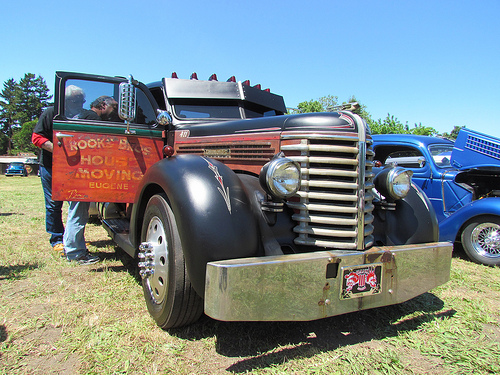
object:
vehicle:
[51, 71, 451, 329]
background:
[0, 0, 500, 268]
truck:
[370, 127, 500, 267]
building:
[0, 156, 38, 176]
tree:
[0, 72, 52, 123]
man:
[32, 84, 87, 251]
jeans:
[62, 201, 89, 260]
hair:
[64, 84, 85, 99]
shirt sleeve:
[32, 132, 48, 148]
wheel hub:
[132, 154, 258, 299]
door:
[51, 71, 163, 202]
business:
[69, 139, 152, 189]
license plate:
[339, 262, 384, 301]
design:
[343, 268, 376, 297]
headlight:
[258, 158, 301, 198]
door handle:
[56, 132, 73, 140]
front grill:
[291, 135, 374, 249]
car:
[5, 162, 28, 177]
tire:
[138, 195, 204, 328]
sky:
[0, 0, 499, 134]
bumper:
[6, 173, 23, 175]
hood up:
[450, 128, 500, 170]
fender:
[203, 242, 453, 323]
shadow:
[164, 292, 455, 373]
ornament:
[327, 102, 361, 112]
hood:
[284, 112, 358, 133]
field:
[0, 176, 499, 374]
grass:
[0, 271, 164, 375]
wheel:
[461, 215, 500, 265]